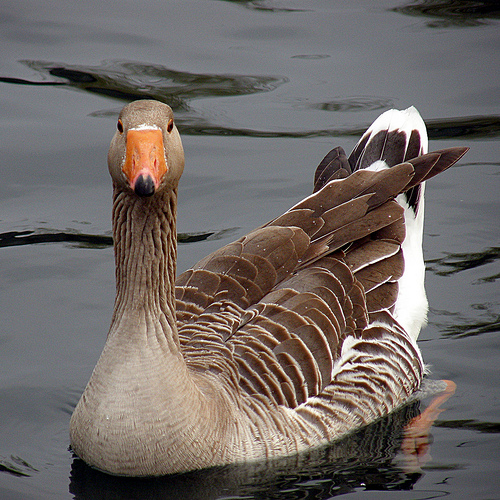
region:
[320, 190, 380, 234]
Brown feather on duck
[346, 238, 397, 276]
Brown feather on duck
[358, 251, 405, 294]
Brown feather on duck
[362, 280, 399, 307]
Brown feather on duck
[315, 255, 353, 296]
Brown feather on duck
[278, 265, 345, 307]
Brown feather on duck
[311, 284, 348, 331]
Brown feather on duck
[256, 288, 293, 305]
Brown feather on duck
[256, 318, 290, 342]
Brown feather on duck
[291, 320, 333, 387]
Brown feather on duck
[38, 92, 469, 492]
This is a bird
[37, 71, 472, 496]
This is a bird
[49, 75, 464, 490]
This is a bird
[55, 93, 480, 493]
This is a bird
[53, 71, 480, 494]
This is a bird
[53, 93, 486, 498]
This is a bird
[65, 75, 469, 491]
This is a bird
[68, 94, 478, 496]
This is a bird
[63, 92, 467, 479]
This is a bird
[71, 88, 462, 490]
This is a bird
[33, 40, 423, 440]
this is a nature photo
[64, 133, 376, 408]
this is a duck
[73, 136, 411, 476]
the duck is brown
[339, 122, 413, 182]
the ducks tail is black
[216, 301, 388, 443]
these are feathers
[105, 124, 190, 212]
this is a the ducks bill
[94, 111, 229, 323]
the ducks is looking at the camera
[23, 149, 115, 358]
the water is very dark